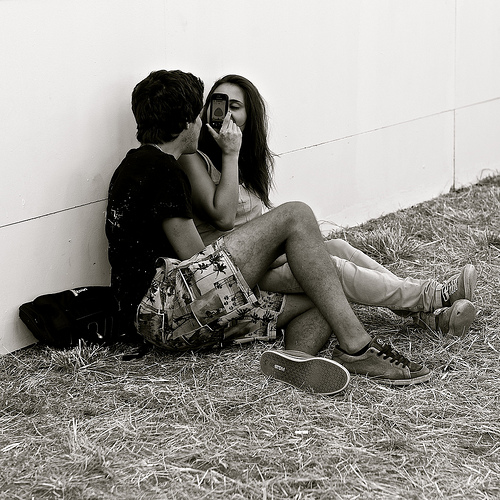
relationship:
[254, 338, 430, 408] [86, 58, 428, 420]
shoes on boy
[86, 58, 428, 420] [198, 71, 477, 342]
boy with girl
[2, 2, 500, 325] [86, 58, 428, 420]
wall behind boy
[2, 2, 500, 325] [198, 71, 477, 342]
wall behind girl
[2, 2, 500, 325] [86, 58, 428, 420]
wall above boy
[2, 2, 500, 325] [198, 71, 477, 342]
wall above girl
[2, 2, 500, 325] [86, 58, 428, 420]
wall beside boy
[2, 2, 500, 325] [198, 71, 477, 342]
wall beside girl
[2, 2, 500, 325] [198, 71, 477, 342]
wall near girl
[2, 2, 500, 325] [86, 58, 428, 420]
wall near boy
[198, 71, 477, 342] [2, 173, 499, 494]
girl on grass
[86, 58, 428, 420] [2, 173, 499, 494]
boy on grass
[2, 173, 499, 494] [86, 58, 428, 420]
grass under boy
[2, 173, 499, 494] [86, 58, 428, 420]
grass below boy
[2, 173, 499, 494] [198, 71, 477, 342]
grass below girl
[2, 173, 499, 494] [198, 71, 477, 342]
grass under girl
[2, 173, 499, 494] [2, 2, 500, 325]
grass under wall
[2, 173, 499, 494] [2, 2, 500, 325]
grass below wall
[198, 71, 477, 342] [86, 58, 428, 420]
girl close to boy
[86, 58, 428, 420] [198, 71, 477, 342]
boy close to girl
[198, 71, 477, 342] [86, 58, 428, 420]
girl with boy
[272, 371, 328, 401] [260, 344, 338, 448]
sole of a shoe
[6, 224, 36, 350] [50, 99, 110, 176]
part of a wall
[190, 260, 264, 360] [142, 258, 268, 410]
part of a short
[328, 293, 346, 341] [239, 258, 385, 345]
part of a leg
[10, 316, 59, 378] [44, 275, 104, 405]
part of a bag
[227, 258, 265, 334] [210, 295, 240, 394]
edge of a short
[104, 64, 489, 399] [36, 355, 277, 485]
couple sitting on grass